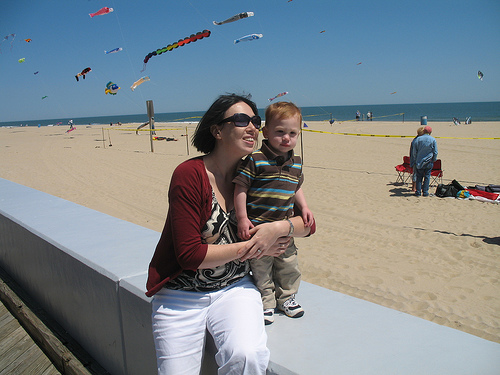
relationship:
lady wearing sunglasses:
[108, 59, 280, 370] [217, 112, 261, 130]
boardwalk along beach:
[0, 283, 112, 373] [1, 117, 499, 339]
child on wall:
[230, 100, 315, 325] [2, 231, 499, 373]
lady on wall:
[141, 90, 317, 375] [4, 178, 495, 372]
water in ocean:
[4, 103, 498, 130] [3, 101, 498, 126]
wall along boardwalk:
[10, 166, 132, 336] [2, 258, 72, 373]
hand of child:
[298, 209, 312, 229] [230, 100, 315, 325]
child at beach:
[232, 101, 314, 323] [2, 100, 499, 373]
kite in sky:
[232, 30, 266, 45] [1, 0, 488, 123]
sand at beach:
[3, 123, 490, 323] [355, 147, 395, 268]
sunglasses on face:
[227, 111, 260, 130] [221, 102, 266, 157]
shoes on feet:
[246, 300, 321, 320] [260, 299, 304, 326]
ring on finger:
[256, 247, 263, 254] [243, 241, 258, 263]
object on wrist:
[280, 215, 295, 240] [282, 220, 290, 232]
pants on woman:
[145, 281, 272, 373] [160, 94, 260, 361]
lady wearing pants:
[141, 90, 317, 375] [147, 292, 273, 374]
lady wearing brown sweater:
[141, 90, 317, 375] [144, 154, 245, 298]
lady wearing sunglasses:
[141, 90, 317, 375] [213, 112, 262, 128]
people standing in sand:
[145, 88, 321, 373] [342, 212, 428, 284]